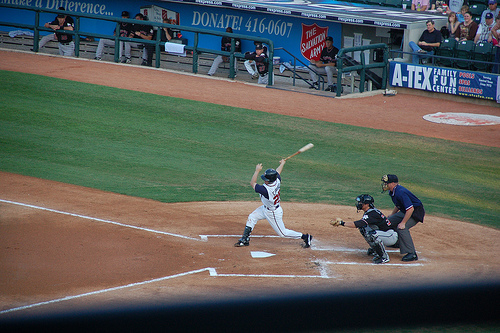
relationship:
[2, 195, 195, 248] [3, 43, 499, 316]
base line on field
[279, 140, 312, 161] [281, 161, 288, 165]
bat in hand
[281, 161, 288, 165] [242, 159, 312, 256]
hand of player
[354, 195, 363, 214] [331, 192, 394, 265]
mask on catcher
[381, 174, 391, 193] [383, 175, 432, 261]
mask on umpire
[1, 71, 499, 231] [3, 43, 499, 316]
grass on field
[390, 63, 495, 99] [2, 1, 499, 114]
advertisement on stands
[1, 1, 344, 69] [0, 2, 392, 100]
advertisement in dugout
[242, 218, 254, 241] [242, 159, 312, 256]
shin protector on player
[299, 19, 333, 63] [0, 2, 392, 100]
logo in dugout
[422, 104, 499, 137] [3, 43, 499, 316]
batter's circle on field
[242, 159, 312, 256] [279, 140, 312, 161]
player swinging bat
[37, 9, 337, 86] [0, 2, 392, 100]
players in dugout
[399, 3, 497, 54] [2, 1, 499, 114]
spectators in stands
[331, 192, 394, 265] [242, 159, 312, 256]
catcher behind player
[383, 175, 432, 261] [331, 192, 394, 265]
umpire behind catcher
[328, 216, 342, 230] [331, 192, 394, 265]
mitt on catcher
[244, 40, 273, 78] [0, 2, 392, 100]
man leaning in dugout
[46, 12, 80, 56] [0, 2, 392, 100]
man leaning in dugout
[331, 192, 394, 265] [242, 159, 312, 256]
catcher squatting behind player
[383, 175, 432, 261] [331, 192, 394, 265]
umpire squatting behind catcher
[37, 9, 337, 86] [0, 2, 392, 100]
players sitting in dugout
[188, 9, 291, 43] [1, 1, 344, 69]
lettering on advertisement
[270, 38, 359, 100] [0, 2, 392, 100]
staircase to dugout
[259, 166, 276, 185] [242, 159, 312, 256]
helmet of player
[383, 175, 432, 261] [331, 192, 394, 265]
umpire and catcher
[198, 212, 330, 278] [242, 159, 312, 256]
batter's box for player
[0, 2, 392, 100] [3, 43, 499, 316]
dugout on field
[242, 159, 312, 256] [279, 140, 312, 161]
player swinging h bat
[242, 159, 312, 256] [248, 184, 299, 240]
player in uniform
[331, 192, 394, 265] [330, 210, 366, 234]
catcher with extended arm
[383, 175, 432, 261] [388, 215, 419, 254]
umpire wearing pants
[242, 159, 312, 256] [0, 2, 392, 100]
player sitting in dugout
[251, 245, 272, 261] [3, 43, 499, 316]
home plate on field